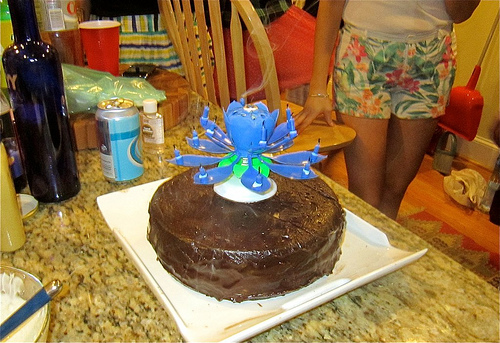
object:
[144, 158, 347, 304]
cake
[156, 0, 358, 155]
chair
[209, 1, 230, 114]
spindle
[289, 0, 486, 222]
woman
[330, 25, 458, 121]
shorts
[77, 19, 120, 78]
cup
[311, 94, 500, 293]
floor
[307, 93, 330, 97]
bracelet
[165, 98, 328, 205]
topper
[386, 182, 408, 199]
knee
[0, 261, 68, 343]
container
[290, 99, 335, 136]
hand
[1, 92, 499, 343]
countertop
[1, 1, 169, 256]
clutter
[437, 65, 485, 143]
dustpan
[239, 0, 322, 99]
smoke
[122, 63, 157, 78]
cell phone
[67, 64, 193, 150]
lazy susan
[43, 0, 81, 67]
bottle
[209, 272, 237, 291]
frosting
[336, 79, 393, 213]
legs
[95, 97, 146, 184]
can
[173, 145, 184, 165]
candle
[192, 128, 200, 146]
candle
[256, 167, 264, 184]
candle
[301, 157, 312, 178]
candle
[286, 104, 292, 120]
candle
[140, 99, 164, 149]
bottle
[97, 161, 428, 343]
white container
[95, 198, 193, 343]
edge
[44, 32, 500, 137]
part